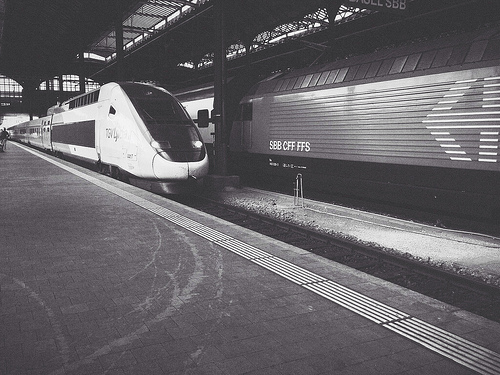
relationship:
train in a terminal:
[7, 78, 212, 198] [6, 8, 482, 362]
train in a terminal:
[14, 78, 219, 189] [6, 8, 482, 362]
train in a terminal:
[132, 33, 470, 219] [6, 8, 482, 362]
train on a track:
[7, 78, 212, 198] [201, 189, 468, 306]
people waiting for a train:
[5, 126, 12, 156] [14, 78, 219, 189]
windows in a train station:
[3, 70, 99, 95] [4, 8, 464, 358]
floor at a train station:
[9, 112, 460, 364] [4, 8, 464, 358]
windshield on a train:
[124, 78, 200, 158] [24, 84, 207, 182]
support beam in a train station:
[202, 42, 245, 182] [6, 5, 496, 372]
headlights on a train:
[146, 136, 211, 156] [7, 78, 212, 198]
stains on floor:
[2, 222, 236, 372] [4, 140, 491, 370]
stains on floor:
[12, 214, 252, 372] [4, 142, 449, 372]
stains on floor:
[12, 214, 252, 372] [4, 140, 491, 370]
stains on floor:
[15, 218, 240, 368] [4, 140, 491, 370]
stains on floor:
[8, 198, 275, 372] [4, 140, 491, 370]